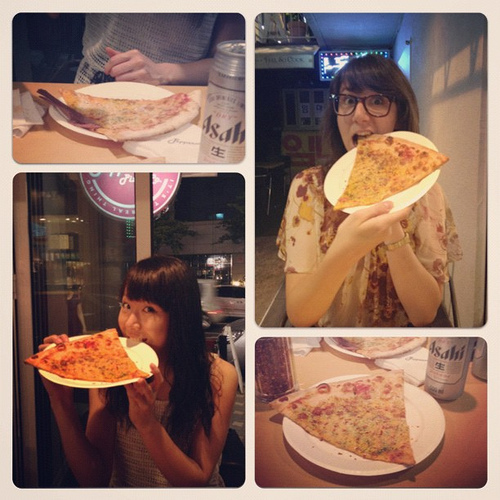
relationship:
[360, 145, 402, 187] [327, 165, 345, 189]
pizza on plate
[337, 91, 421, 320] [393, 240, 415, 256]
woman wearing watch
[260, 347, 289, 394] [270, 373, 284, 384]
container of peppers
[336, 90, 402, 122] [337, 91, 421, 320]
glasses of woman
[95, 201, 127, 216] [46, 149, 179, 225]
lettering on sign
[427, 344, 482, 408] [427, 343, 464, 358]
can of asahi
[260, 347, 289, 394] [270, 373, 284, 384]
container in peppers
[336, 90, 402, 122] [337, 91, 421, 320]
glasses on woman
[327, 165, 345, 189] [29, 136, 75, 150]
plate on table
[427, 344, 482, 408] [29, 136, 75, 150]
can on table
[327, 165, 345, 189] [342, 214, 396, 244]
plate on hand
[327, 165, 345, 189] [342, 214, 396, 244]
plate in hand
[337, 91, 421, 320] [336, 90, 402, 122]
woman wearing glasses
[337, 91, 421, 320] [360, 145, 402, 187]
woman biting pizza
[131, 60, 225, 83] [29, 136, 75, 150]
arm on table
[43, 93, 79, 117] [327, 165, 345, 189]
knife on plate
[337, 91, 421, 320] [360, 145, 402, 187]
woman holding pizza